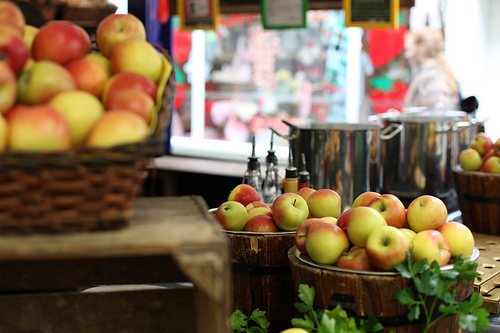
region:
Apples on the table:
[0, 0, 164, 145]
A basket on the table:
[0, 160, 142, 227]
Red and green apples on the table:
[0, 1, 157, 149]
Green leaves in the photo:
[228, 262, 488, 331]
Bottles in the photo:
[281, 162, 311, 192]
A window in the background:
[200, 37, 318, 117]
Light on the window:
[222, 49, 335, 97]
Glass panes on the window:
[215, 41, 333, 108]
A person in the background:
[398, 32, 447, 117]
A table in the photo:
[0, 186, 242, 268]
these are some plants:
[276, 252, 499, 328]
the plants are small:
[261, 263, 486, 332]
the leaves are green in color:
[415, 272, 435, 292]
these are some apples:
[3, 2, 149, 139]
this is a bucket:
[317, 273, 359, 288]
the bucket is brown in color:
[265, 241, 293, 265]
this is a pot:
[306, 124, 381, 178]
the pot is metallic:
[310, 144, 325, 153]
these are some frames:
[173, 3, 406, 26]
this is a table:
[481, 241, 495, 287]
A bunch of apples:
[1, 54, 131, 138]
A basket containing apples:
[9, 159, 99, 213]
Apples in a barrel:
[315, 228, 390, 273]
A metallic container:
[321, 145, 356, 185]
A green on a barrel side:
[410, 265, 441, 305]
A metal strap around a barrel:
[388, 318, 398, 325]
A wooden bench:
[148, 225, 216, 253]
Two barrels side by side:
[257, 247, 292, 282]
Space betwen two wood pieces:
[103, 285, 168, 287]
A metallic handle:
[378, 125, 398, 137]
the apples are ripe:
[303, 201, 485, 257]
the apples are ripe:
[228, 183, 318, 228]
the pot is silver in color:
[306, 125, 386, 183]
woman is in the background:
[389, 30, 463, 108]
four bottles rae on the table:
[232, 139, 311, 193]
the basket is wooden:
[247, 232, 479, 324]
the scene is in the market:
[1, 5, 496, 327]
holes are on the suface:
[476, 225, 498, 295]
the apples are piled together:
[6, 8, 186, 153]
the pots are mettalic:
[288, 111, 469, 196]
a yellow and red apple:
[215, 200, 246, 227]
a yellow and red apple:
[246, 211, 275, 234]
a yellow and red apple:
[271, 191, 308, 229]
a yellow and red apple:
[306, 188, 342, 219]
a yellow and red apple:
[304, 223, 349, 263]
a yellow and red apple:
[345, 205, 387, 243]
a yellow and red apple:
[366, 224, 406, 269]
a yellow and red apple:
[339, 247, 371, 270]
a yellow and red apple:
[411, 230, 451, 266]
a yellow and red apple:
[438, 218, 475, 259]